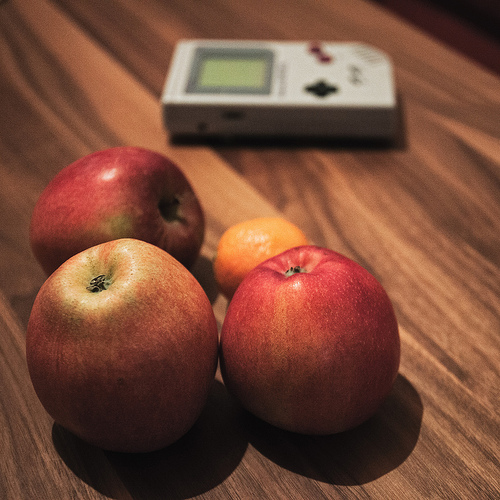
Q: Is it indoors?
A: Yes, it is indoors.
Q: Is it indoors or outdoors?
A: It is indoors.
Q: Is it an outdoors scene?
A: No, it is indoors.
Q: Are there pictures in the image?
A: No, there are no pictures.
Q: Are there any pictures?
A: No, there are no pictures.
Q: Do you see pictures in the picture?
A: No, there are no pictures.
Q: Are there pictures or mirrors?
A: No, there are no pictures or mirrors.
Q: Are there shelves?
A: No, there are no shelves.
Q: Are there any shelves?
A: No, there are no shelves.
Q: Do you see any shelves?
A: No, there are no shelves.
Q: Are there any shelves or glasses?
A: No, there are no shelves or glasses.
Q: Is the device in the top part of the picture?
A: Yes, the device is in the top of the image.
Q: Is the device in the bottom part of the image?
A: No, the device is in the top of the image.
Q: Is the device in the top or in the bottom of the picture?
A: The device is in the top of the image.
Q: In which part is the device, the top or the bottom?
A: The device is in the top of the image.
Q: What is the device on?
A: The device is on the table.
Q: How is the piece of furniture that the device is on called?
A: The piece of furniture is a table.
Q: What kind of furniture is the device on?
A: The device is on the table.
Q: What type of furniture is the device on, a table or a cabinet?
A: The device is on a table.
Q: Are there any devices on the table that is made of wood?
A: Yes, there is a device on the table.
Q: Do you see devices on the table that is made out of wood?
A: Yes, there is a device on the table.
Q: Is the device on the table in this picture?
A: Yes, the device is on the table.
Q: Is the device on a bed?
A: No, the device is on the table.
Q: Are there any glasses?
A: No, there are no glasses.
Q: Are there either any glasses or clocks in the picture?
A: No, there are no glasses or clocks.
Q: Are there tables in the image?
A: Yes, there is a table.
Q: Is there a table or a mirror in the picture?
A: Yes, there is a table.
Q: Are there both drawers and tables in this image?
A: No, there is a table but no drawers.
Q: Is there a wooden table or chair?
A: Yes, there is a wood table.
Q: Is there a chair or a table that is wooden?
A: Yes, the table is wooden.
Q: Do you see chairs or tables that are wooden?
A: Yes, the table is wooden.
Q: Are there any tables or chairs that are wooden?
A: Yes, the table is wooden.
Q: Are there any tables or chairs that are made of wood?
A: Yes, the table is made of wood.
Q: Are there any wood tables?
A: Yes, there is a wood table.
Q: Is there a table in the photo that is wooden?
A: Yes, there is a table that is wooden.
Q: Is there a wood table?
A: Yes, there is a table that is made of wood.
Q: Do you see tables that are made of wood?
A: Yes, there is a table that is made of wood.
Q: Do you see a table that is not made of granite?
A: Yes, there is a table that is made of wood.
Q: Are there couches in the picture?
A: No, there are no couches.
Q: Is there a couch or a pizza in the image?
A: No, there are no couches or pizzas.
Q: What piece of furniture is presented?
A: The piece of furniture is a table.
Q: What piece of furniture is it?
A: The piece of furniture is a table.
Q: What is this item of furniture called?
A: This is a table.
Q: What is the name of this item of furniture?
A: This is a table.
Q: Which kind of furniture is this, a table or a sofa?
A: This is a table.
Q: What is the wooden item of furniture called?
A: The piece of furniture is a table.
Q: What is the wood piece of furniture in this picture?
A: The piece of furniture is a table.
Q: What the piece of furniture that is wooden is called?
A: The piece of furniture is a table.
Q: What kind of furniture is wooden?
A: The furniture is a table.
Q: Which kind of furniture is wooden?
A: The furniture is a table.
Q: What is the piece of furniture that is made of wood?
A: The piece of furniture is a table.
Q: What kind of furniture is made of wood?
A: The furniture is a table.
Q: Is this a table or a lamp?
A: This is a table.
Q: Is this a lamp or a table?
A: This is a table.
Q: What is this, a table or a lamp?
A: This is a table.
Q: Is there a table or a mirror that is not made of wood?
A: No, there is a table but it is made of wood.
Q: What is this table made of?
A: The table is made of wood.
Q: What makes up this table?
A: The table is made of wood.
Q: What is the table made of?
A: The table is made of wood.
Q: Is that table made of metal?
A: No, the table is made of wood.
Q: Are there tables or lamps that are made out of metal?
A: No, there is a table but it is made of wood.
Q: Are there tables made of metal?
A: No, there is a table but it is made of wood.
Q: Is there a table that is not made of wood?
A: No, there is a table but it is made of wood.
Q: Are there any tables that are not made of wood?
A: No, there is a table but it is made of wood.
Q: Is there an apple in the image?
A: Yes, there is an apple.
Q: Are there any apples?
A: Yes, there is an apple.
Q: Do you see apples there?
A: Yes, there is an apple.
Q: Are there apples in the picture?
A: Yes, there is an apple.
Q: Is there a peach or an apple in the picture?
A: Yes, there is an apple.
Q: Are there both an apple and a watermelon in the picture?
A: No, there is an apple but no watermelons.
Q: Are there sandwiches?
A: No, there are no sandwiches.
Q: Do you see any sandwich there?
A: No, there are no sandwiches.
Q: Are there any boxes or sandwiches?
A: No, there are no sandwiches or boxes.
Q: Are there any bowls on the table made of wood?
A: No, there is an apple on the table.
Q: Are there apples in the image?
A: Yes, there is an apple.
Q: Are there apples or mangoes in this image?
A: Yes, there is an apple.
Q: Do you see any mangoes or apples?
A: Yes, there is an apple.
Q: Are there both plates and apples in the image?
A: No, there is an apple but no plates.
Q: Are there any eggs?
A: No, there are no eggs.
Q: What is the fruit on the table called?
A: The fruit is an apple.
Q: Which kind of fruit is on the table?
A: The fruit is an apple.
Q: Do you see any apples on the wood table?
A: Yes, there is an apple on the table.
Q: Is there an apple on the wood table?
A: Yes, there is an apple on the table.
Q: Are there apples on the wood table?
A: Yes, there is an apple on the table.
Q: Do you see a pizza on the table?
A: No, there is an apple on the table.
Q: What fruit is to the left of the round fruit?
A: The fruit is an apple.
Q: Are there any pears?
A: No, there are no pears.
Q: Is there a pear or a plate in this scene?
A: No, there are no pears or plates.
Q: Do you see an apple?
A: Yes, there is an apple.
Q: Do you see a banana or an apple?
A: Yes, there is an apple.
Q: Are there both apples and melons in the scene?
A: No, there is an apple but no melons.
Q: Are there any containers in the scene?
A: No, there are no containers.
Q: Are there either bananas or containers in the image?
A: No, there are no containers or bananas.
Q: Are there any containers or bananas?
A: No, there are no containers or bananas.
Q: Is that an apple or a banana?
A: That is an apple.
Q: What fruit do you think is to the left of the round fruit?
A: The fruit is an apple.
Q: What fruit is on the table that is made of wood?
A: The fruit is an apple.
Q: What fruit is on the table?
A: The fruit is an apple.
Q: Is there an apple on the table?
A: Yes, there is an apple on the table.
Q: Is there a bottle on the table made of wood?
A: No, there is an apple on the table.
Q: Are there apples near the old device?
A: Yes, there is an apple near the device.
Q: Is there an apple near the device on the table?
A: Yes, there is an apple near the device.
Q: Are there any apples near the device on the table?
A: Yes, there is an apple near the device.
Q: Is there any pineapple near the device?
A: No, there is an apple near the device.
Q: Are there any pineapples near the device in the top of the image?
A: No, there is an apple near the device.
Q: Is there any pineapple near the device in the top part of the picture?
A: No, there is an apple near the device.